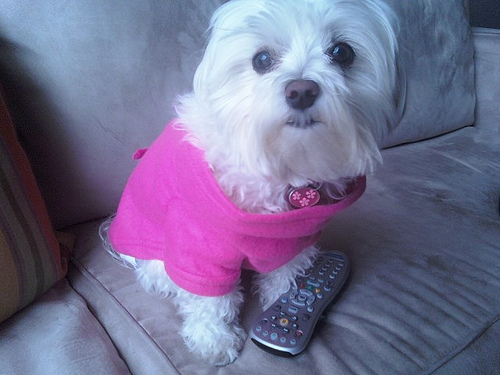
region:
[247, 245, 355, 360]
silver remote with many buttons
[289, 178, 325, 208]
a pink dog collar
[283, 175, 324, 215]
round collar with purple flowers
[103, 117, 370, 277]
a pink sweater on a dog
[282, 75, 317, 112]
a brown dog nose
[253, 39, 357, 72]
two brown eyes on a dog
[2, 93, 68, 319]
side of a striped pillow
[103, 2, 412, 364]
a white fluffy dog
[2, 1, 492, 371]
a dog sitting on the couch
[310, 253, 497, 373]
wrinkles on the couch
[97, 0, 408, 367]
a little white dog sitting on the couch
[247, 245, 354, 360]
the remote control for the TV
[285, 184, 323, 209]
a pink tag on the dog's collar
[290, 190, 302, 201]
a pink flower on the dog tag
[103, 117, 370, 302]
hot pink dog clothing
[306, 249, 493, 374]
wrinkles on the couch cushion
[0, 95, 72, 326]
a striped pillow on the couch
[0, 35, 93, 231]
the pillow's shadow on the couch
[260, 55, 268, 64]
a reflection of light in the dog's eye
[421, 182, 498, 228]
stains on the couch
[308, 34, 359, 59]
eye of the dog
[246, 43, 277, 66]
eye of the dog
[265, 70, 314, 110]
nose of the dog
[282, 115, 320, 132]
mouth of the dog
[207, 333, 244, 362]
paw of the dog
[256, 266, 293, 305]
paw of the dog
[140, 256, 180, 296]
paw of the dog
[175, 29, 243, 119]
ear of the dog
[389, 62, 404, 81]
ear of the dog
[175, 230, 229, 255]
the shirt is pink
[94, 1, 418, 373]
the dog is white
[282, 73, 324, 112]
nose of dog is black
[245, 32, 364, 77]
eyes of dog are round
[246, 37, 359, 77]
eyes are color black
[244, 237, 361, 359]
control remote over couch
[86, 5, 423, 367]
dog sits on couch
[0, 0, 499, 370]
couch is color brown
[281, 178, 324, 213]
pink tag of dog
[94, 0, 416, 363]
dog has pink dress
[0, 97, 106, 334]
a cushion on side the dog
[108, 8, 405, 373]
small dog sitting on couch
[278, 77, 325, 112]
tiny black nose of dog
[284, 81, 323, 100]
small nostrils of dog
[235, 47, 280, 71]
black eye of dog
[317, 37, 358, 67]
black eye of dog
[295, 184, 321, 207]
pink on dogs collar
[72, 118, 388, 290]
small pink sweater on dog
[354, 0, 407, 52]
white furry ear of dog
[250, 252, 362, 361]
remote control on the couch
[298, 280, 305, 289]
red button on remote